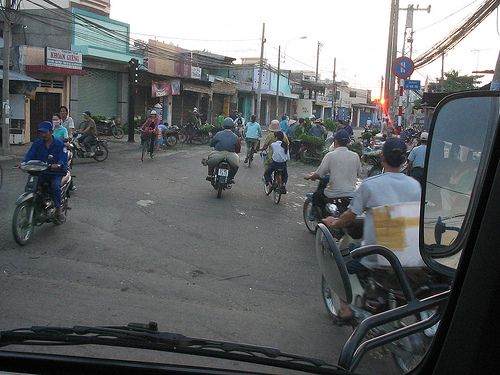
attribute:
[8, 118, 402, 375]
street — tar, busy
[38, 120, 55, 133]
hat — blue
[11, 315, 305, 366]
wiper — black, metal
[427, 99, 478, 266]
mirror — black, circular, large, oblong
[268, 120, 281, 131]
hat — pink, white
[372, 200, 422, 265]
bag — white, brown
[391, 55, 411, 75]
sign — blue, red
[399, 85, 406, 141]
pole — striped, red, white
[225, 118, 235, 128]
helmet — gray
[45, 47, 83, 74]
sign — white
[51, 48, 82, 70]
letters — blue, red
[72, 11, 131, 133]
building — light green, dark green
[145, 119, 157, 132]
shirt — pink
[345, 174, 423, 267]
shirt — grey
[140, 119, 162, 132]
shirt — orange